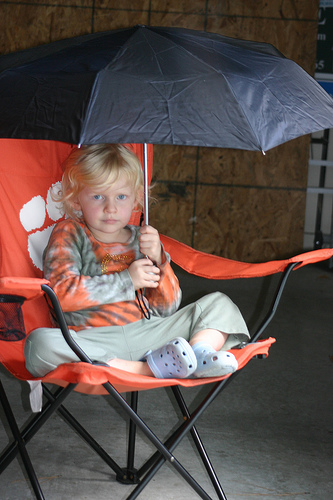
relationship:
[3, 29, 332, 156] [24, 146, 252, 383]
black umbrella opened over child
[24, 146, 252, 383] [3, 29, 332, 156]
small child holds up black umbrella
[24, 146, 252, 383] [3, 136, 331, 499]
child sits on orange chair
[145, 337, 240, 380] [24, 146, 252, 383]
grey croc shoes on foot of child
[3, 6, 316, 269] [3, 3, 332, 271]
plywood against wall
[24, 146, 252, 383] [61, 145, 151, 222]
child has wavy blonde hair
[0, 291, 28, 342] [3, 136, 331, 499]
mesh cup holder on orange chair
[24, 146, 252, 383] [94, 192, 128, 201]
child has blue eyes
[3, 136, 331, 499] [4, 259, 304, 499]
orange chair has black metal legs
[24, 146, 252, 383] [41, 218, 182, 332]
child has an orange/grey shirt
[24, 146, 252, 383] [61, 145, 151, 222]
child has blonde hair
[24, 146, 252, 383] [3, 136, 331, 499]
child siting deep in orange chair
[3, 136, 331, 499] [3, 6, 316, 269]
orange chair in front of plywood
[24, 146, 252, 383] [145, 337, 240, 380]
child wears plastic clog shoes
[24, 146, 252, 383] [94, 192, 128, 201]
child looks with light blue eyes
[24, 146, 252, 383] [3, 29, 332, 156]
child holds open black umbrella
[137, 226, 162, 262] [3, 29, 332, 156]
child's hand holds up black umbrella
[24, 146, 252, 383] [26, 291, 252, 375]
child wears light green toddler pants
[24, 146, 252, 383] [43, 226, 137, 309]
child has long sleeve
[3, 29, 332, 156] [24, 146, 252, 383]
black umbrella over child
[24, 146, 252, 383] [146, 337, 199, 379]
child has on white shoe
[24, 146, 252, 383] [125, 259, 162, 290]
child has small hand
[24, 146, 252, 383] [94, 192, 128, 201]
boy has blue eyes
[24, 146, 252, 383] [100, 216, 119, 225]
child has a closed mouth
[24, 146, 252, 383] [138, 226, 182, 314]
child holds up h arm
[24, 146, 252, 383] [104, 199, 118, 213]
child has a small nose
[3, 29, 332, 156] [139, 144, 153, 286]
black umbrella has a metal post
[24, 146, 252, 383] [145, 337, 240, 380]
child wearing white crocs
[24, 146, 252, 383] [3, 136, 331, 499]
child sitting on an orange chair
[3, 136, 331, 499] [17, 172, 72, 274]
orange chair has a paw print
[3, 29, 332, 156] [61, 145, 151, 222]
black umbrella above child blonde hair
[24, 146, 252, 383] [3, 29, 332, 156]
child holds onto a black umbrella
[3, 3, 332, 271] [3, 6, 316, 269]
wall has brown plywood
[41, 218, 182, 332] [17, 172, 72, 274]
orange/grey shirt in front of paw print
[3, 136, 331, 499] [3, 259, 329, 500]
orange chair on cement floor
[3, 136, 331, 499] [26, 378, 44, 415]
orange chair has a white tag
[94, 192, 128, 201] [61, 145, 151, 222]
blue eyes of child under blonde hair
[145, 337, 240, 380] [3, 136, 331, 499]
grey croc shoes are on orange chair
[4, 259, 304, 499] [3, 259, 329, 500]
black metal legs are on cement floor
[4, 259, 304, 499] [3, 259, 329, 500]
black metal legs sit on cement floor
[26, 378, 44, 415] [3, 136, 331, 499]
tag hangs down from orange chair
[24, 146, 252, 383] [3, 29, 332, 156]
child keeps open black umbrella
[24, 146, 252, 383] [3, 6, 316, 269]
child sits in front of plywood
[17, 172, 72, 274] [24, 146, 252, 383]
paw print behind child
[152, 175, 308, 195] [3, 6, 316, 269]
blue line on plywood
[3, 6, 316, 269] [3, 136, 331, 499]
plywood wall sits behind orange chair